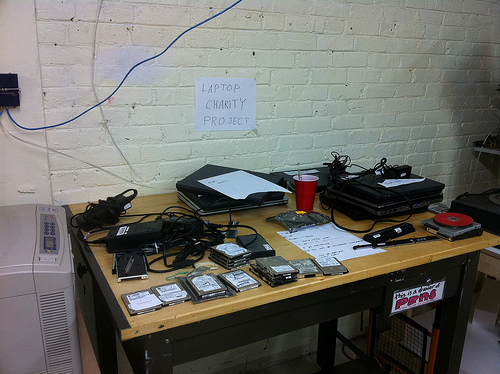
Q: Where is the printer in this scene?
A: To the left.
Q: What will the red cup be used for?
A: A pen holder.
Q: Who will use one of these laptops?
A: A charity client.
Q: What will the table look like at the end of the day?
A: Empty.